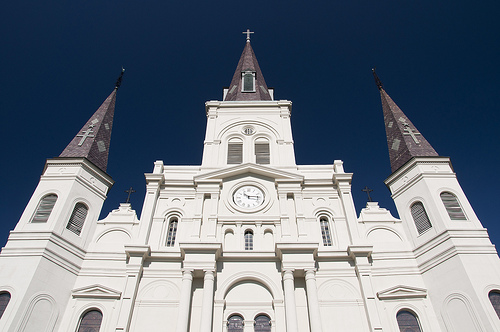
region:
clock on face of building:
[220, 176, 274, 213]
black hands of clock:
[240, 189, 262, 203]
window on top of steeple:
[235, 66, 260, 91]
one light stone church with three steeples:
[3, 15, 498, 328]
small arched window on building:
[239, 226, 259, 248]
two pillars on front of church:
[172, 268, 219, 329]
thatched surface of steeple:
[372, 85, 442, 170]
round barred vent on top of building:
[239, 123, 257, 137]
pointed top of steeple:
[362, 64, 385, 87]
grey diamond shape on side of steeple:
[387, 133, 405, 156]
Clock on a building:
[227, 177, 266, 211]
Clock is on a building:
[228, 178, 276, 210]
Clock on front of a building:
[230, 175, 267, 211]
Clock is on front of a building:
[227, 177, 267, 207]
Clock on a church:
[228, 180, 267, 210]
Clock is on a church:
[230, 180, 267, 210]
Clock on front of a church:
[229, 180, 269, 211]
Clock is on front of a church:
[229, 180, 271, 212]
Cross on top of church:
[240, 24, 257, 44]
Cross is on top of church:
[239, 25, 258, 42]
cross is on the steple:
[239, 24, 256, 46]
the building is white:
[146, 274, 168, 306]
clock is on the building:
[239, 187, 260, 208]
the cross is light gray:
[403, 124, 420, 144]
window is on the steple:
[238, 67, 256, 93]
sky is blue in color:
[141, 32, 176, 65]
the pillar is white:
[178, 290, 191, 316]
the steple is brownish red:
[383, 98, 395, 115]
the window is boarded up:
[406, 200, 434, 235]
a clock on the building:
[226, 179, 270, 211]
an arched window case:
[241, 227, 256, 250]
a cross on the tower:
[73, 125, 94, 148]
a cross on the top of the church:
[241, 28, 254, 40]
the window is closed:
[439, 190, 466, 224]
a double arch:
[223, 311, 273, 330]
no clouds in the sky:
[2, 6, 495, 231]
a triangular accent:
[376, 283, 428, 298]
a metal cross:
[124, 187, 134, 204]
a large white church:
[2, 27, 498, 327]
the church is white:
[25, 25, 472, 326]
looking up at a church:
[43, 12, 485, 249]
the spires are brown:
[44, 25, 496, 256]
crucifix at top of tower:
[231, 16, 276, 61]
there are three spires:
[48, 38, 453, 250]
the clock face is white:
[213, 141, 310, 226]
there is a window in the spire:
[208, 8, 313, 142]